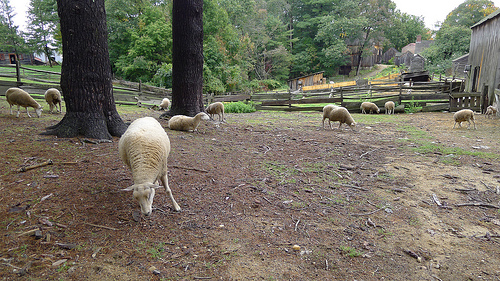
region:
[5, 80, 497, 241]
several sheep in a pen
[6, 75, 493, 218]
several sheep eating grass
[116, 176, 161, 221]
the head of a sheep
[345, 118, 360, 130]
the head of a sheep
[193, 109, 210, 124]
the head of a sheep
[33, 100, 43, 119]
the head of a sheep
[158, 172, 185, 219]
the leg of a sheep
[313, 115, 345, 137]
the legs of a sheep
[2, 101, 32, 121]
the legs of a sheep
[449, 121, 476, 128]
the leg of a sheep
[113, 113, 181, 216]
sheep beding over for food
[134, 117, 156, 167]
wool on sheep's back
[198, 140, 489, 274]
ground with little to no grass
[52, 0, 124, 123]
tree with bark in tact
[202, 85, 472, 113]
wooden fence to keep sheep indoors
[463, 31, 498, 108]
barn to keep supplies or people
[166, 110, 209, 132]
sheep sitting down resting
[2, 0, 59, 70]
another area of land sectioned off by fence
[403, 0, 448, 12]
blue skies indicate day time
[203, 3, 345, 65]
trees for shade and oxygen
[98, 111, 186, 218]
a white sheep chewing a stick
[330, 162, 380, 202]
gray sticks scattered on the ground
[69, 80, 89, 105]
rough black tree bark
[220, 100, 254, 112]
a patch of green shrubbery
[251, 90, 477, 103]
a wooden fence surrounding the sheep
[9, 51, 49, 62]
a dilapidated house in the distance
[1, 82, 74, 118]
two sheep sniffin the ground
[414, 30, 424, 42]
the brick chimney on a roof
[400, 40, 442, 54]
the roof of a house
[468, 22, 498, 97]
a gray wooden barn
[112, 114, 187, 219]
white sheep grazing in the dirt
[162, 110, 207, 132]
sheep laying in front of tree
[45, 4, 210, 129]
two tree trunks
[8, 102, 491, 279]
barren ground with scattered grass patches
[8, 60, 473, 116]
wood fence around field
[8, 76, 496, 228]
group of sheep grazing from the ground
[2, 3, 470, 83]
trees behind the fenceline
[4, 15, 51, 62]
house on the hill on left side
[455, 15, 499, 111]
barn beside area sheep are grazing in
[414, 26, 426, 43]
chimney of house in the distance